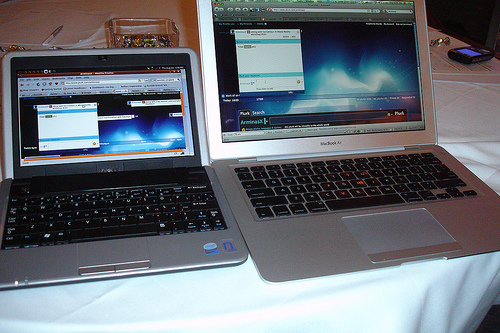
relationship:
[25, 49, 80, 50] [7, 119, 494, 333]
pen on table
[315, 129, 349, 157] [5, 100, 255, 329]
sign on laptop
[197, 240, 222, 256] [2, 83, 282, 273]
software sticker on laptop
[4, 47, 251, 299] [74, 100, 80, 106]
notebook computer has camera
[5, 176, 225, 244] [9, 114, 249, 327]
keyboard on laptop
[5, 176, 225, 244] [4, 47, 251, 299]
keyboard on notebook computer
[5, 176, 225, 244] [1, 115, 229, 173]
keyboard on laptop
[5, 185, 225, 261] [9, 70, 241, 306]
keyboard on laptop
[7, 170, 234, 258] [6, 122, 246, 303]
keyboard on laptop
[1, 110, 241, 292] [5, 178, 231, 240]
keyboard on laptop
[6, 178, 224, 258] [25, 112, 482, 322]
cellphone on table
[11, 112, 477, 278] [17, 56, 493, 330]
computers on table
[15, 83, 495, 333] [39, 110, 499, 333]
table has tablecloth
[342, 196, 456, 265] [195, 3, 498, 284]
mouse buttons on a notebook computer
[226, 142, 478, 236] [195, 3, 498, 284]
keyboard on a notebook computer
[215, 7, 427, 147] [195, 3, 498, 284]
display screen on a notebook computer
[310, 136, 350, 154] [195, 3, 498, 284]
manufacturer logo on a notebook computer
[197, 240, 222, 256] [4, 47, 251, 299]
software sticker on a notebook computer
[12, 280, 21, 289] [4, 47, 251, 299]
indicator light on a notebook computer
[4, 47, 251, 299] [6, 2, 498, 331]
notebook computer on a tabletop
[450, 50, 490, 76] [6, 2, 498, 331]
phone sutting on a tabletop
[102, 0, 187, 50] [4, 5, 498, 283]
container behind computers